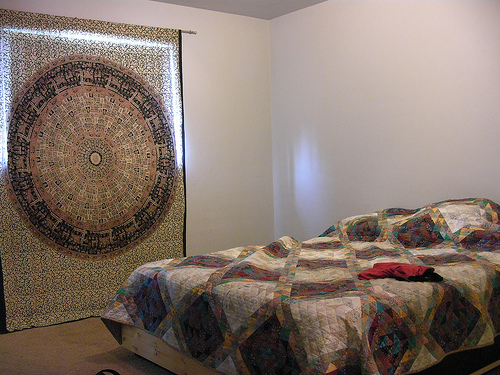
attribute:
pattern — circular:
[14, 61, 192, 265]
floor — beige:
[35, 331, 129, 371]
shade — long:
[1, 27, 179, 315]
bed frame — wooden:
[111, 312, 225, 372]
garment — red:
[363, 254, 441, 295]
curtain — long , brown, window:
[4, 8, 199, 339]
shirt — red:
[352, 255, 450, 290]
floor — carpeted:
[1, 326, 128, 372]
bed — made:
[123, 190, 498, 357]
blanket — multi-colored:
[99, 194, 496, 369]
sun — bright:
[5, 21, 184, 171]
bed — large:
[109, 199, 497, 374]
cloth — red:
[358, 259, 443, 283]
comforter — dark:
[120, 205, 499, 365]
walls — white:
[242, 52, 402, 163]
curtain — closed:
[15, 40, 178, 253]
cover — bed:
[87, 195, 498, 373]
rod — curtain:
[177, 27, 200, 45]